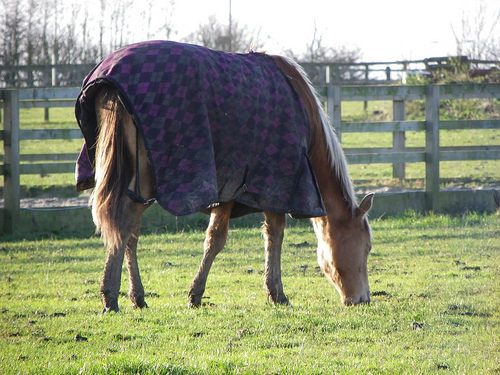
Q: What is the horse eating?
A: Grass.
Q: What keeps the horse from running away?
A: The fence.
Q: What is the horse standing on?
A: Grass.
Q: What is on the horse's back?
A: A blanket.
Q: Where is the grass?
A: In the pasture.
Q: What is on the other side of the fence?
A: Trees.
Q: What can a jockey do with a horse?
A: Ride it.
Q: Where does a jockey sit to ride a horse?
A: On the horse's back.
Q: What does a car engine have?
A: Horsepower.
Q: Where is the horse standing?
A: Pen.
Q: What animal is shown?
A: Horse.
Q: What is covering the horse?
A: Blanket.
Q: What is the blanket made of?
A: Argyle.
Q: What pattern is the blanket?
A: Diamonds.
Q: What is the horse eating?
A: Grass.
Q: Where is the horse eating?
A: Field.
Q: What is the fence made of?
A: Wood.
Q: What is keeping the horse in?
A: Wooden fence.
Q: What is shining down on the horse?
A: Sunlight.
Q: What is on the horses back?
A: A blanket.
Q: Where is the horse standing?
A: The grass.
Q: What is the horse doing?
A: Eating.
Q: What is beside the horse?
A: The gate.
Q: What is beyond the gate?
A: Trees.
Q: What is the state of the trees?
A: Leafless.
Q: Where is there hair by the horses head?
A: Its neck.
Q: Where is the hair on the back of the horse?
A: Its tail.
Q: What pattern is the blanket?
A: Checkered.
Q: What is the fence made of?
A: Wood.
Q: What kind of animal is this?
A: Horse.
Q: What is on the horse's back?
A: Blanket.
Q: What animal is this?
A: Horse.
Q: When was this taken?
A: During the day.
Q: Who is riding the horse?
A: No one.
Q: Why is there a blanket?
A: To stay warm.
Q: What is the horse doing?
A: Grazing.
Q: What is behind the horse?
A: Fence.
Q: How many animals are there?
A: One.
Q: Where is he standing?
A: In the grass.